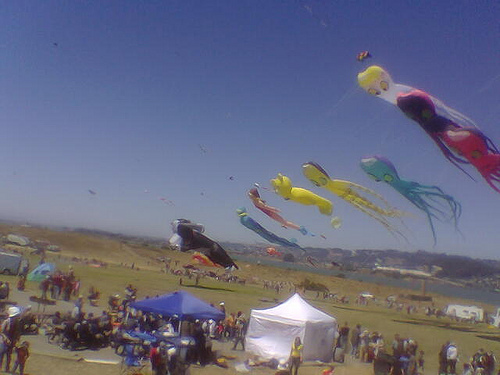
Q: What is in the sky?
A: Kites.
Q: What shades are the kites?
A: Multicolored.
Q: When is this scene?
A: Afternoon.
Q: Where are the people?
A: Under tent.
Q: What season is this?
A: Summer.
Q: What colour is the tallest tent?
A: White.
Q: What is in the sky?
A: A flying kite.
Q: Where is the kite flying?
A: In the sky.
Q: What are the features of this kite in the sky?
A: It's a blue kite with yellow eyes.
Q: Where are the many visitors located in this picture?
A: On a grassy ground.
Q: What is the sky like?
A: Slightly misty blue and sunny.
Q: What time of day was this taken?
A: Afternoon.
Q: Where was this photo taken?
A: In a field.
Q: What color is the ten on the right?
A: White.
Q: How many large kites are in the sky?
A: Eight.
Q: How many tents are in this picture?
A: Two.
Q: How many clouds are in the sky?
A: None.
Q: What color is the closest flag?
A: Red.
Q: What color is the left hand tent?
A: Blue.